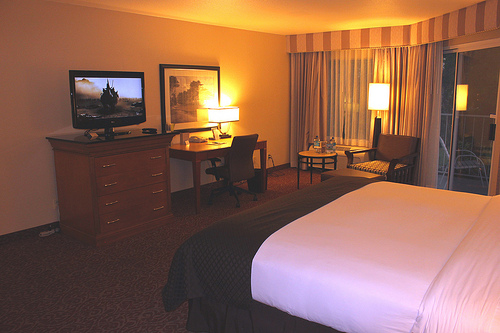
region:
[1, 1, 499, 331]
A hotel room.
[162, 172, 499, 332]
Bed with pink sheets and a brown blanket.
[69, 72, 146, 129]
A flat screen television set.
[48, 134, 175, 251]
A brown wooden dresser.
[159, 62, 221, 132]
A picture in a brown frame hanging on the wall.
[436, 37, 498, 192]
Glass doors that lead out to patio.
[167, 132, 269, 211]
A brown desk with a brown chair.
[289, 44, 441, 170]
Sheer brown window drapes.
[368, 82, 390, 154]
Lamp with a white lamp shade.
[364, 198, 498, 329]
white bedding in a hotel room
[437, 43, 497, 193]
sliding glass door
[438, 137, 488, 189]
patio chair outside on a deck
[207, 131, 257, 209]
wheeled desk chair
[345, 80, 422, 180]
floor lamp next to an armchair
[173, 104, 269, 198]
lamp on a desk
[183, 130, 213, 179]
telephone on the desk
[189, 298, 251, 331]
dark bedskirt on the bed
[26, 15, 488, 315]
The inside of a motel room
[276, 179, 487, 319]
White sheets on a bed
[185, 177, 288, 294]
A brown bedspread on bed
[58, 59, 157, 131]
A tv on top of a dresser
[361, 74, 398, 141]
A tall floor lamp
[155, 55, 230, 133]
A large picture on wall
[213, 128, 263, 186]
A chair under the desk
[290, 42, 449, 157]
A beige curtain over windows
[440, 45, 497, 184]
A glass sliding door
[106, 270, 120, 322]
There is a nice floor here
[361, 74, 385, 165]
There is a standing lamp here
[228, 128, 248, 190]
There is a chair here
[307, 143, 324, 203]
There is an endtable here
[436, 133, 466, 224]
There is a chair on the deck out here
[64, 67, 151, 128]
A TV is on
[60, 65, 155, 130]
A television is on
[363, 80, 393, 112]
A lamp in the room is on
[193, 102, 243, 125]
A lamp in the room is on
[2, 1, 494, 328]
The room is dimly lit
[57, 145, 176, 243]
Brown wooden cabinets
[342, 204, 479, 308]
White and organized bed spread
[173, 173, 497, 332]
black and white sheets on bed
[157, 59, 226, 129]
picture hanging in the wall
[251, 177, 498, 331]
white blanket on the bet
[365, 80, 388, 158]
lamp sitting on the floor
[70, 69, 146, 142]
television sitting on the dresser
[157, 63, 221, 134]
picture hanging on the wall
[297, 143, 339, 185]
table next to the window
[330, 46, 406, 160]
sheer curtains hanging in front of the window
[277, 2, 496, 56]
valance hanging over the window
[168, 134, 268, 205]
table holding a lamp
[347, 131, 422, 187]
chair against the curtains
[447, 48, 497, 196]
glass sliding door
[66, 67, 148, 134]
television is on the dresser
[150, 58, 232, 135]
picture above the desk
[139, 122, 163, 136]
remote is next to the television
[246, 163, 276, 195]
trash can next to the desk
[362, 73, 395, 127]
lamp is turned on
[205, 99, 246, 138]
lamp on the desk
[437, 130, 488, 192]
chair on the balcony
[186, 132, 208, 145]
telephone on the desk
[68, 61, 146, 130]
television is on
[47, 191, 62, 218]
outlet behind dresser